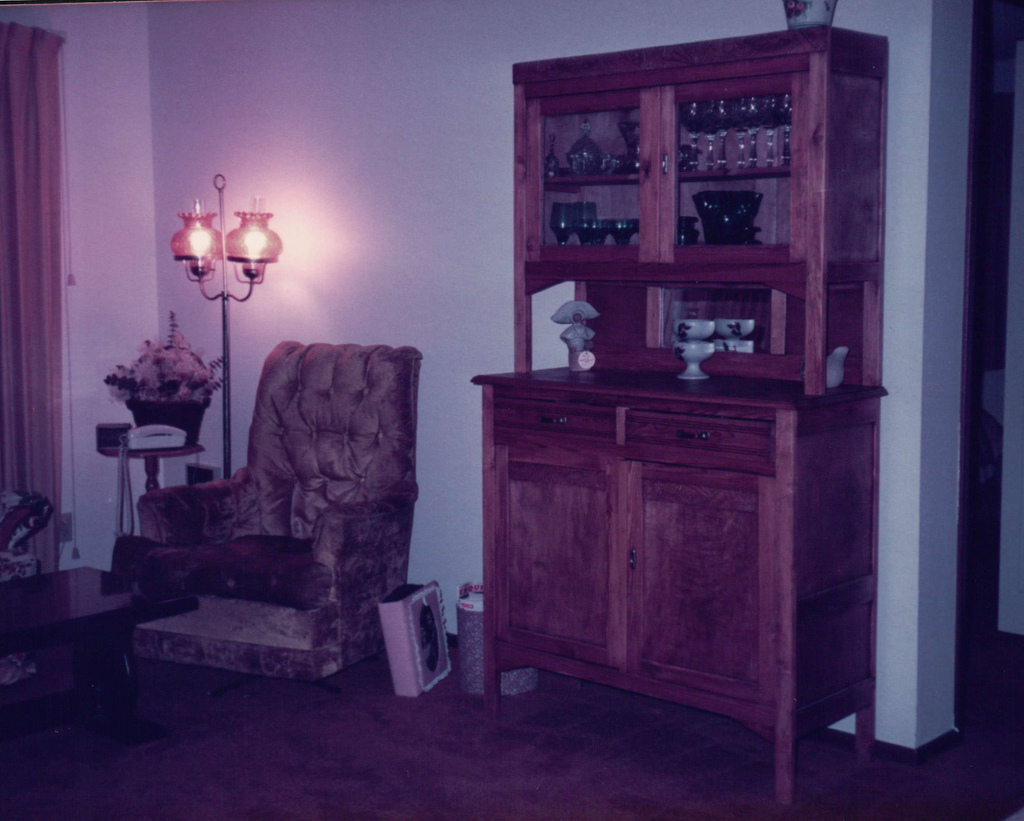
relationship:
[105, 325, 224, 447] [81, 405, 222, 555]
flower arrangement on table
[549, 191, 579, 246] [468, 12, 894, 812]
glass in cabinet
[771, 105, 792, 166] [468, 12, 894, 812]
glass in cabinet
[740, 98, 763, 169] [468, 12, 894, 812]
glass in cabinet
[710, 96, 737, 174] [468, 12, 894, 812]
glass in cabinet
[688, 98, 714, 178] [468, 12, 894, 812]
glass in cabinet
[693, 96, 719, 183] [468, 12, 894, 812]
glass in cabinet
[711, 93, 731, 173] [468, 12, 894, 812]
glass in cabinet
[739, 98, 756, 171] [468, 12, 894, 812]
glass in cabinet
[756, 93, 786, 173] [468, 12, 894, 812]
glass in cabinet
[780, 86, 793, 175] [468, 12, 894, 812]
glass in cabinet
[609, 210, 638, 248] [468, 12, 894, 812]
glass in cabinet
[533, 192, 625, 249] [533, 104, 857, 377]
glass in cabinet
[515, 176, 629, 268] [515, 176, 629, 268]
glass in cabinet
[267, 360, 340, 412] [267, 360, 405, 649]
button on recliner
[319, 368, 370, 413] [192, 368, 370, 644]
button on recliner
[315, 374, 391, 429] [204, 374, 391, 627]
button on recliner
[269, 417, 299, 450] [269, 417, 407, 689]
button on recliner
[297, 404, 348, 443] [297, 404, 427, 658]
button on recliner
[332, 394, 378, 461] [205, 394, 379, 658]
button on recliner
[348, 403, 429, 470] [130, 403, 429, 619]
button on recliner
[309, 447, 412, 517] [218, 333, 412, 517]
button on recliner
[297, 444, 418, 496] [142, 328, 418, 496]
button on recliner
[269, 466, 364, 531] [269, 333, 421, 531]
button on recliner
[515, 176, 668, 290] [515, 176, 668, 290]
glass in hutch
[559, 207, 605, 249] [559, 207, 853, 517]
glass in hutch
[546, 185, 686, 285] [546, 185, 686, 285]
glass in hutch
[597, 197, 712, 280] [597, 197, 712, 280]
glass in hutch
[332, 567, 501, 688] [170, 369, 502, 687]
album next to chair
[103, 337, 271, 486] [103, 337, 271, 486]
basket of flowers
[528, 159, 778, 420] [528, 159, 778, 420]
dishware in cupboard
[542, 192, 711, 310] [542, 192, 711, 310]
cabinet has glass